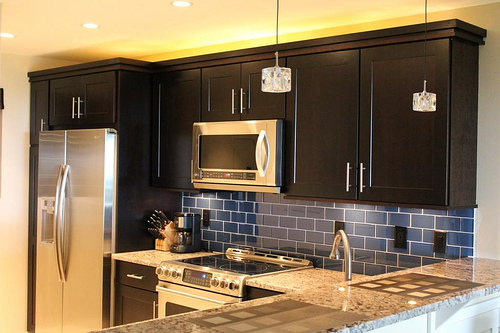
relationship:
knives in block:
[136, 204, 173, 237] [161, 221, 185, 256]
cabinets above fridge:
[15, 69, 143, 138] [28, 124, 121, 222]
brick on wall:
[261, 210, 297, 245] [206, 199, 367, 242]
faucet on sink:
[324, 219, 359, 298] [319, 239, 343, 299]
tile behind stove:
[215, 208, 238, 239] [169, 251, 232, 316]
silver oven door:
[148, 280, 212, 309] [140, 276, 215, 332]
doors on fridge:
[28, 146, 118, 330] [28, 124, 121, 222]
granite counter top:
[321, 290, 371, 311] [294, 273, 332, 294]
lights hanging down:
[249, 59, 319, 101] [258, 52, 300, 118]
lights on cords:
[249, 59, 319, 101] [273, 9, 285, 64]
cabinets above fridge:
[298, 37, 455, 256] [28, 124, 121, 222]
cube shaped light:
[411, 90, 453, 120] [254, 63, 303, 81]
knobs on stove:
[155, 262, 181, 282] [169, 251, 232, 316]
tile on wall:
[215, 208, 238, 239] [206, 199, 367, 242]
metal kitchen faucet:
[331, 236, 369, 268] [324, 219, 359, 298]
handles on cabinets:
[339, 160, 368, 209] [298, 37, 455, 256]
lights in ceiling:
[249, 59, 319, 101] [308, 11, 362, 37]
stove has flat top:
[148, 245, 315, 317] [167, 244, 304, 271]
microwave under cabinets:
[182, 115, 296, 200] [105, 16, 482, 207]